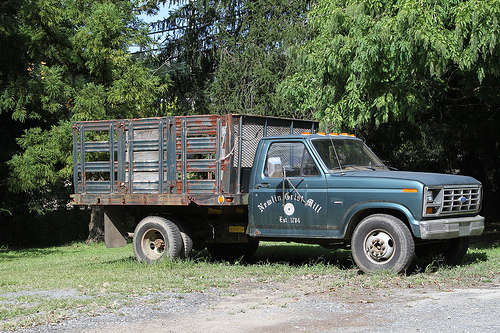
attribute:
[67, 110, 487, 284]
truck — blue, ford, old, green, rusty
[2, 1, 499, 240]
trees — green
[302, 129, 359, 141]
lights — orange